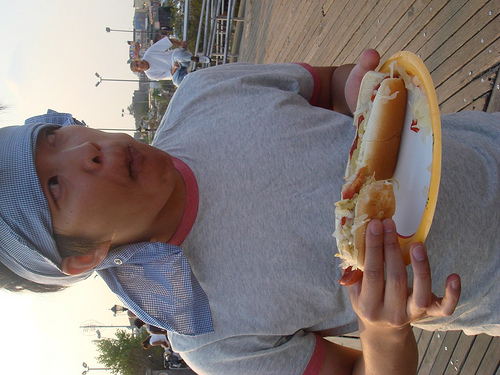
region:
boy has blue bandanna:
[0, 103, 64, 267]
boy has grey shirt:
[145, 125, 495, 307]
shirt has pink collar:
[154, 144, 236, 253]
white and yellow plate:
[356, 64, 439, 226]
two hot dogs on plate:
[324, 70, 409, 305]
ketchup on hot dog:
[331, 80, 381, 170]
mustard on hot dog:
[335, 89, 377, 181]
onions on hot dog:
[326, 80, 411, 172]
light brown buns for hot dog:
[347, 81, 404, 196]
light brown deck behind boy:
[263, 3, 402, 65]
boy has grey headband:
[0, 108, 65, 278]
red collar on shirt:
[155, 107, 216, 254]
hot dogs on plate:
[339, 67, 411, 265]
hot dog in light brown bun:
[340, 54, 386, 221]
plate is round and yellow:
[370, 47, 443, 272]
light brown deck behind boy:
[312, 15, 493, 62]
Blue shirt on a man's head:
[0, 117, 217, 337]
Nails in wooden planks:
[459, 8, 498, 110]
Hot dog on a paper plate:
[345, 68, 403, 184]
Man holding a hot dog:
[327, 182, 399, 295]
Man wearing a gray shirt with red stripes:
[149, 59, 497, 374]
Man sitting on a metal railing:
[117, 32, 209, 89]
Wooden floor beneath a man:
[177, 2, 499, 374]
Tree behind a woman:
[92, 330, 184, 373]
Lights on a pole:
[91, 73, 176, 90]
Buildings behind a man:
[124, 0, 156, 132]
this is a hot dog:
[335, 79, 417, 219]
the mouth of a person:
[110, 134, 160, 182]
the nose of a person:
[83, 137, 114, 179]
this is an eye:
[46, 167, 64, 202]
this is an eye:
[44, 116, 69, 152]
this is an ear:
[60, 234, 107, 279]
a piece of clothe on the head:
[7, 147, 34, 241]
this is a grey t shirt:
[246, 202, 289, 272]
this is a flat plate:
[411, 151, 440, 191]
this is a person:
[131, 25, 192, 80]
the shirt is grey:
[199, 100, 496, 315]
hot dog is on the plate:
[327, 78, 412, 174]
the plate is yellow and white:
[401, 112, 448, 232]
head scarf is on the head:
[0, 123, 63, 300]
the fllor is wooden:
[271, 20, 354, 50]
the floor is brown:
[284, 16, 356, 49]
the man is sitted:
[128, 40, 215, 84]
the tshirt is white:
[147, 43, 179, 75]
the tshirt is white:
[146, 332, 168, 347]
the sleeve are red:
[300, 334, 333, 374]